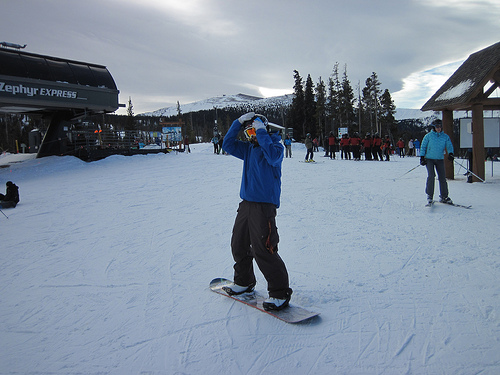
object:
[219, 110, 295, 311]
person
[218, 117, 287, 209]
coat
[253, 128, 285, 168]
arm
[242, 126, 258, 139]
goggles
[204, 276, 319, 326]
snowboard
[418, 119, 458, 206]
person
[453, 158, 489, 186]
ski pole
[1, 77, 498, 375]
snow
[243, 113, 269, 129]
helmet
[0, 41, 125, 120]
bus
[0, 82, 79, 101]
zephyr express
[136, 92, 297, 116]
mountain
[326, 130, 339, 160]
person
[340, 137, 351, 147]
jacket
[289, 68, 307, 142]
pine tree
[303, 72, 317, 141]
pine tree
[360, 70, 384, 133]
pine tree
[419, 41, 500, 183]
shelter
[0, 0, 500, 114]
cloud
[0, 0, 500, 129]
sky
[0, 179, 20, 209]
person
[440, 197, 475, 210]
on skies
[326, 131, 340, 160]
uniform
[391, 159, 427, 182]
ski pole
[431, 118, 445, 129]
helmet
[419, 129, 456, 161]
coat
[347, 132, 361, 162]
person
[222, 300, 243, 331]
tracks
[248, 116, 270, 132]
glove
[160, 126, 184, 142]
sign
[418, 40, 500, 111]
roof